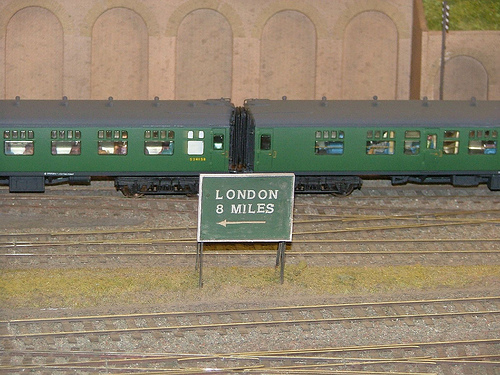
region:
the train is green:
[26, 116, 483, 185]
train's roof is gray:
[15, 92, 464, 138]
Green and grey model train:
[1, 97, 489, 197]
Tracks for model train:
[1, 295, 499, 343]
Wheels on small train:
[118, 177, 196, 200]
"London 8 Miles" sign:
[196, 170, 296, 243]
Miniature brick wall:
[1, 0, 429, 97]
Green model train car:
[0, 96, 235, 195]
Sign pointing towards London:
[196, 170, 296, 290]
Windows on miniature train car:
[312, 129, 499, 158]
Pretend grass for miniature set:
[3, 263, 496, 303]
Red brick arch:
[163, 0, 244, 100]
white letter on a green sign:
[264, 185, 281, 201]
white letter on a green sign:
[257, 187, 269, 202]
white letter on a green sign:
[245, 187, 257, 202]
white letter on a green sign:
[234, 184, 247, 201]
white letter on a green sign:
[223, 188, 236, 202]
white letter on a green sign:
[211, 187, 227, 204]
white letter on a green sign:
[265, 200, 277, 215]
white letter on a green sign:
[254, 201, 268, 216]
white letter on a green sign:
[247, 200, 255, 215]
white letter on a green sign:
[240, 202, 250, 215]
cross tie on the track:
[361, 302, 373, 332]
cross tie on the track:
[310, 310, 329, 333]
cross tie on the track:
[272, 312, 285, 334]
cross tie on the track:
[233, 311, 250, 338]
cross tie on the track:
[212, 315, 228, 335]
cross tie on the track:
[192, 317, 206, 338]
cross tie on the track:
[163, 316, 187, 341]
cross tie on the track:
[122, 317, 144, 338]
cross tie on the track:
[106, 325, 133, 346]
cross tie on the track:
[145, 319, 162, 335]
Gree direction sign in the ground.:
[219, 185, 293, 251]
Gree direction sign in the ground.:
[31, 340, 37, 372]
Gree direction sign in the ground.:
[95, 347, 110, 371]